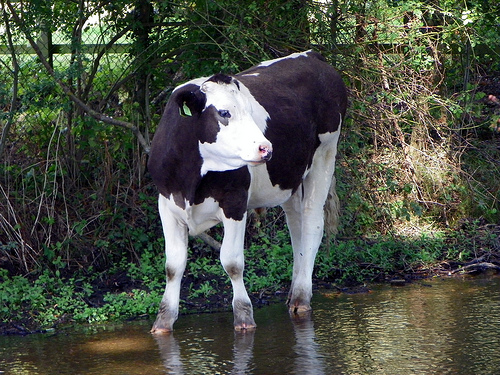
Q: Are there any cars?
A: No, there are no cars.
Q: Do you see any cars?
A: No, there are no cars.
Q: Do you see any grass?
A: Yes, there is grass.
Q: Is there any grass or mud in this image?
A: Yes, there is grass.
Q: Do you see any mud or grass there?
A: Yes, there is grass.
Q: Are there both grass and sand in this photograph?
A: No, there is grass but no sand.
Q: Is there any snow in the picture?
A: No, there is no snow.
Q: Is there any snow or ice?
A: No, there are no snow or ice.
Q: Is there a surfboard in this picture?
A: No, there are no surfboards.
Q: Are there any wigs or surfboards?
A: No, there are no surfboards or wigs.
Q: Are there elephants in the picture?
A: No, there are no elephants.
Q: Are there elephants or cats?
A: No, there are no elephants or cats.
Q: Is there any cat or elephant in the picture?
A: No, there are no elephants or cats.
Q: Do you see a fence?
A: Yes, there is a fence.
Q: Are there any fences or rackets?
A: Yes, there is a fence.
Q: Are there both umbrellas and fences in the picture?
A: No, there is a fence but no umbrellas.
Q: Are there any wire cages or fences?
A: Yes, there is a wire fence.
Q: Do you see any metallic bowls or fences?
A: Yes, there is a metal fence.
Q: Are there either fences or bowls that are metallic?
A: Yes, the fence is metallic.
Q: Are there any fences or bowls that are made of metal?
A: Yes, the fence is made of metal.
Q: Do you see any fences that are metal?
A: Yes, there is a metal fence.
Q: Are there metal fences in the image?
A: Yes, there is a metal fence.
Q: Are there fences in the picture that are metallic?
A: Yes, there is a fence that is metallic.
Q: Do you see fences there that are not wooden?
A: Yes, there is a metallic fence.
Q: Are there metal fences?
A: Yes, there is a fence that is made of metal.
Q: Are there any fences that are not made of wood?
A: Yes, there is a fence that is made of metal.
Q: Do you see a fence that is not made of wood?
A: Yes, there is a fence that is made of metal.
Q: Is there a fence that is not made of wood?
A: Yes, there is a fence that is made of metal.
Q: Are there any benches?
A: No, there are no benches.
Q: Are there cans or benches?
A: No, there are no benches or cans.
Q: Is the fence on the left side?
A: Yes, the fence is on the left of the image.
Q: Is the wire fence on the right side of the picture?
A: No, the fence is on the left of the image.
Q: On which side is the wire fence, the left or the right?
A: The fence is on the left of the image.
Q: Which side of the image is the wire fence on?
A: The fence is on the left of the image.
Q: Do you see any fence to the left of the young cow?
A: Yes, there is a fence to the left of the cow.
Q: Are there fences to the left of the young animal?
A: Yes, there is a fence to the left of the cow.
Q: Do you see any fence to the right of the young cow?
A: No, the fence is to the left of the cow.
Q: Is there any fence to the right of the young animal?
A: No, the fence is to the left of the cow.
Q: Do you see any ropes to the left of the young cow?
A: No, there is a fence to the left of the cow.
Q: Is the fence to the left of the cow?
A: Yes, the fence is to the left of the cow.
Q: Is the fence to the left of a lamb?
A: No, the fence is to the left of the cow.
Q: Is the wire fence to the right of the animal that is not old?
A: No, the fence is to the left of the cow.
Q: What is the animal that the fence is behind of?
A: The animal is a cow.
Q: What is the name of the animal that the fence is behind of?
A: The animal is a cow.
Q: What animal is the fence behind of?
A: The fence is behind the cow.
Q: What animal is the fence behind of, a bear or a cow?
A: The fence is behind a cow.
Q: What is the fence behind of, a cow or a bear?
A: The fence is behind a cow.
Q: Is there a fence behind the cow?
A: Yes, there is a fence behind the cow.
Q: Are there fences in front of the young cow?
A: No, the fence is behind the cow.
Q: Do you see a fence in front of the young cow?
A: No, the fence is behind the cow.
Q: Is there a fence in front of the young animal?
A: No, the fence is behind the cow.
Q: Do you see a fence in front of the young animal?
A: No, the fence is behind the cow.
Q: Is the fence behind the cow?
A: Yes, the fence is behind the cow.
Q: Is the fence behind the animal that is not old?
A: Yes, the fence is behind the cow.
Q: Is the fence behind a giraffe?
A: No, the fence is behind the cow.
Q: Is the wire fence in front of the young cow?
A: No, the fence is behind the cow.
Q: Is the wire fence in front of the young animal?
A: No, the fence is behind the cow.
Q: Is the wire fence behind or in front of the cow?
A: The fence is behind the cow.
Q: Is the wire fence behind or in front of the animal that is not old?
A: The fence is behind the cow.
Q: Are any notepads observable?
A: No, there are no notepads.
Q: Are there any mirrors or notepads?
A: No, there are no notepads or mirrors.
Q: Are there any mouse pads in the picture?
A: No, there are no mouse pads.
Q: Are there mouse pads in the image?
A: No, there are no mouse pads.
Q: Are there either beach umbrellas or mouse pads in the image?
A: No, there are no mouse pads or beach umbrellas.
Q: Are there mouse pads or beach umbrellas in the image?
A: No, there are no mouse pads or beach umbrellas.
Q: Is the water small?
A: Yes, the water is small.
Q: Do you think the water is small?
A: Yes, the water is small.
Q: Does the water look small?
A: Yes, the water is small.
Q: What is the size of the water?
A: The water is small.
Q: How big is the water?
A: The water is small.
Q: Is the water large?
A: No, the water is small.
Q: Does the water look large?
A: No, the water is small.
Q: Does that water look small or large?
A: The water is small.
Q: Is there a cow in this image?
A: Yes, there is a cow.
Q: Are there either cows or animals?
A: Yes, there is a cow.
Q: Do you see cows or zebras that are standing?
A: Yes, the cow is standing.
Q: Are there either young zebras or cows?
A: Yes, there is a young cow.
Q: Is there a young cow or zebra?
A: Yes, there is a young cow.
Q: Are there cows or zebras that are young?
A: Yes, the cow is young.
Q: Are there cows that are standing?
A: Yes, there is a cow that is standing.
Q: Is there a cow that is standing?
A: Yes, there is a cow that is standing.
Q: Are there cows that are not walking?
A: Yes, there is a cow that is standing.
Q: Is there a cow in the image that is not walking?
A: Yes, there is a cow that is standing.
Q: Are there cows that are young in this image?
A: Yes, there is a young cow.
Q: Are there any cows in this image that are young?
A: Yes, there is a cow that is young.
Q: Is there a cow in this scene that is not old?
A: Yes, there is an young cow.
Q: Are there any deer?
A: No, there are no deer.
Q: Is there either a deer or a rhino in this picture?
A: No, there are no deer or rhinos.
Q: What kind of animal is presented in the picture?
A: The animal is a cow.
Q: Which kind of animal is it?
A: The animal is a cow.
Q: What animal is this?
A: This is a cow.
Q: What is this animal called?
A: This is a cow.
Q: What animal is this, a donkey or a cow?
A: This is a cow.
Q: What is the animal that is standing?
A: The animal is a cow.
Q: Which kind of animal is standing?
A: The animal is a cow.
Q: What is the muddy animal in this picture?
A: The animal is a cow.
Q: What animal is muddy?
A: The animal is a cow.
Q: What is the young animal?
A: The animal is a cow.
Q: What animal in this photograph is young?
A: The animal is a cow.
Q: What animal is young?
A: The animal is a cow.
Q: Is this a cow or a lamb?
A: This is a cow.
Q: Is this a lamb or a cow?
A: This is a cow.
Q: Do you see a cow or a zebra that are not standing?
A: No, there is a cow but it is standing.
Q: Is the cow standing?
A: Yes, the cow is standing.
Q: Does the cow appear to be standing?
A: Yes, the cow is standing.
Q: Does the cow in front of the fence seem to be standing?
A: Yes, the cow is standing.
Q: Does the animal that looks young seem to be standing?
A: Yes, the cow is standing.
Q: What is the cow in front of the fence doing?
A: The cow is standing.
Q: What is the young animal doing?
A: The cow is standing.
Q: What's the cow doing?
A: The cow is standing.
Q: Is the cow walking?
A: No, the cow is standing.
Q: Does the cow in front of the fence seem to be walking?
A: No, the cow is standing.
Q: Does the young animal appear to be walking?
A: No, the cow is standing.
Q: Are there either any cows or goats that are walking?
A: No, there is a cow but it is standing.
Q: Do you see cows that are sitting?
A: No, there is a cow but it is standing.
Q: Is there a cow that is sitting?
A: No, there is a cow but it is standing.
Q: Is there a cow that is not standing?
A: No, there is a cow but it is standing.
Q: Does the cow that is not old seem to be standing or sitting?
A: The cow is standing.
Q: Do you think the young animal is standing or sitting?
A: The cow is standing.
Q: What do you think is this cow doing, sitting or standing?
A: The cow is standing.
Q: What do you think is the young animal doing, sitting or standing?
A: The cow is standing.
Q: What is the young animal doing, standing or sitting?
A: The cow is standing.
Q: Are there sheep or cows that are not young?
A: No, there is a cow but it is young.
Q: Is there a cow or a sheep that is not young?
A: No, there is a cow but it is young.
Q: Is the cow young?
A: Yes, the cow is young.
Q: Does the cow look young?
A: Yes, the cow is young.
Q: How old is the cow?
A: The cow is young.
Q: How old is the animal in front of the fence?
A: The cow is young.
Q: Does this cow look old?
A: No, the cow is young.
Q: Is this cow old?
A: No, the cow is young.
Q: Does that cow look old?
A: No, the cow is young.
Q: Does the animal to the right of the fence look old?
A: No, the cow is young.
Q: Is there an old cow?
A: No, there is a cow but it is young.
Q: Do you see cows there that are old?
A: No, there is a cow but it is young.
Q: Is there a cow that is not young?
A: No, there is a cow but it is young.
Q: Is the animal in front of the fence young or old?
A: The cow is young.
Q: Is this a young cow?
A: Yes, this is a young cow.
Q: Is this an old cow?
A: No, this is a young cow.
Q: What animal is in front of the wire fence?
A: The cow is in front of the fence.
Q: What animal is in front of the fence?
A: The cow is in front of the fence.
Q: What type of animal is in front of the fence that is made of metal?
A: The animal is a cow.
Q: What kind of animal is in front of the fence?
A: The animal is a cow.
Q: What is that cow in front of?
A: The cow is in front of the fence.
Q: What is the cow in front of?
A: The cow is in front of the fence.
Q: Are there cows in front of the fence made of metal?
A: Yes, there is a cow in front of the fence.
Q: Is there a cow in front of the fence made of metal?
A: Yes, there is a cow in front of the fence.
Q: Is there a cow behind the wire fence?
A: No, the cow is in front of the fence.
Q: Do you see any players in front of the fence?
A: No, there is a cow in front of the fence.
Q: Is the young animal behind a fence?
A: No, the cow is in front of a fence.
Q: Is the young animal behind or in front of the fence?
A: The cow is in front of the fence.